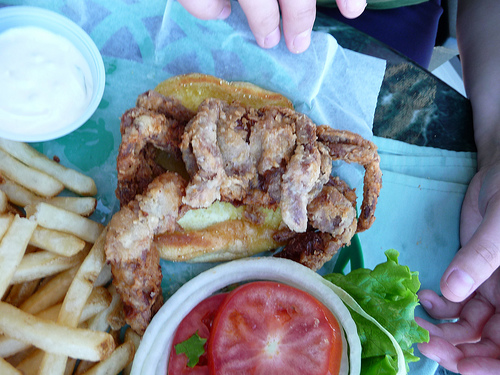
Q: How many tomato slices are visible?
A: 2.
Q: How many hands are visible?
A: 2.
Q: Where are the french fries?
A: Left of the other vegetables.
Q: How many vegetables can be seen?
A: 4.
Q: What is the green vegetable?
A: Lettuce.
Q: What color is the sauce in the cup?
A: White.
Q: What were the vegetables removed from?
A: Sandwich.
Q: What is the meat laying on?
A: Bun.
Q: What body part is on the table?
A: Hands.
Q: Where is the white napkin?
A: Under the man's hand.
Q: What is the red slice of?
A: Tomato.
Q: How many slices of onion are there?
A: Three.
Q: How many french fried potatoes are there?
A: There are several.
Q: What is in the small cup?
A: Sauce.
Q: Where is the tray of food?
A: On the table.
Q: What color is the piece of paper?
A: White.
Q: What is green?
A: A lettuce leaf.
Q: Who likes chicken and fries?
A: A young, Caucasian person with short, clean nails that are handling a wrapper.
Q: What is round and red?
A: A slice of tomato.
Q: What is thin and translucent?
A: The wrapper beneath the food.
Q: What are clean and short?
A: The diners fingernails.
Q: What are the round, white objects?
A: Onion slices.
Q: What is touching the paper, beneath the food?
A: Diner's right hand.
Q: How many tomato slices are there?
A: Two.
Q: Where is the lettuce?
A: Under the tomatoes and onions.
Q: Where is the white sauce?
A: To the left.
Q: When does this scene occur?
A: At lunchtime.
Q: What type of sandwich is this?
A: Fried seafood.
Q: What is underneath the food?
A: Paper wrapper.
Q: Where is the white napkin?
A: To the right.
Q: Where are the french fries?
A: To the left of the sandwich.